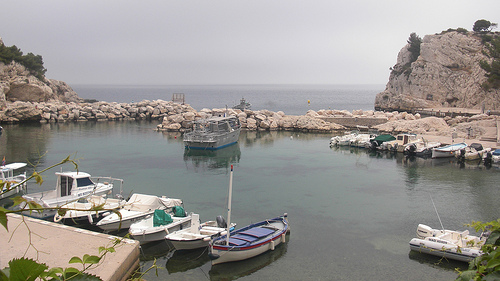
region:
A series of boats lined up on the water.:
[0, 157, 311, 279]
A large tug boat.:
[178, 105, 244, 159]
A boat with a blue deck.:
[208, 163, 298, 266]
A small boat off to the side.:
[394, 210, 484, 277]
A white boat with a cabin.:
[23, 168, 116, 211]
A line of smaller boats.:
[333, 121, 495, 175]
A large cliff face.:
[378, 30, 498, 117]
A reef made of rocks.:
[33, 101, 160, 126]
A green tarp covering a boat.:
[151, 207, 172, 224]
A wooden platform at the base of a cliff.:
[415, 100, 482, 125]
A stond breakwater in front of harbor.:
[0, 95, 493, 141]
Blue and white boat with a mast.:
[208, 164, 290, 266]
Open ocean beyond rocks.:
[51, 82, 406, 114]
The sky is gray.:
[1, 1, 498, 83]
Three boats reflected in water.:
[133, 239, 285, 279]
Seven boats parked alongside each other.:
[0, 162, 292, 264]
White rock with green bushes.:
[376, 20, 499, 112]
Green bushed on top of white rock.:
[1, 31, 56, 100]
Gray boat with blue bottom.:
[182, 109, 247, 149]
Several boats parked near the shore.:
[327, 122, 499, 169]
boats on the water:
[138, 195, 310, 277]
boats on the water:
[113, 176, 221, 269]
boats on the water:
[32, 163, 111, 225]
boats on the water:
[369, 205, 483, 271]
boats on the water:
[325, 109, 481, 190]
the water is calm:
[247, 150, 299, 194]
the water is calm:
[81, 120, 160, 177]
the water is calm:
[288, 146, 400, 241]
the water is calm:
[252, 152, 339, 234]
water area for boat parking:
[2, 113, 497, 278]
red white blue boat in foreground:
[207, 207, 294, 267]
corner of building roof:
[2, 205, 149, 280]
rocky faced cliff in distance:
[370, 19, 498, 123]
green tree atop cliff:
[470, 18, 492, 38]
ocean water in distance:
[57, 77, 392, 110]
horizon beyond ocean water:
[67, 77, 391, 90]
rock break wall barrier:
[5, 94, 425, 133]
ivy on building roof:
[1, 225, 130, 279]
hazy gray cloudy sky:
[3, 5, 498, 97]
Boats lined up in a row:
[5, 153, 309, 260]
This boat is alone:
[170, 114, 267, 160]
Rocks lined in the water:
[0, 22, 430, 164]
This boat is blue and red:
[229, 199, 309, 267]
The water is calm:
[284, 153, 389, 210]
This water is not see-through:
[286, 155, 366, 210]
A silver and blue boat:
[175, 111, 263, 156]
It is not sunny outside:
[102, 12, 267, 57]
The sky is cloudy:
[122, 14, 302, 79]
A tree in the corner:
[5, 145, 130, 278]